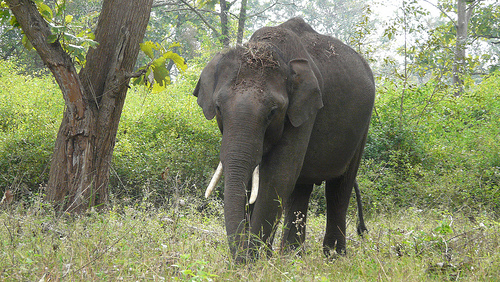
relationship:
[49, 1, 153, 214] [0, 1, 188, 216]
tree trunk of tree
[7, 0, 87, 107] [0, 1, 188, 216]
branch of tree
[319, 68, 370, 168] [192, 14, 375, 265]
side of elephant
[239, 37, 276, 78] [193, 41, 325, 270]
debris sitting on top elephant's head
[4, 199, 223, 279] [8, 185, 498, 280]
plants on ground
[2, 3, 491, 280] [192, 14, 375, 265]
picture has elephant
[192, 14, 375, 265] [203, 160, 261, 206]
elephant has elephant's tusk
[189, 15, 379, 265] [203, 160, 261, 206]
elephant has elephant's tusk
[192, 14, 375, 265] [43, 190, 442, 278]
elephant walking in grass